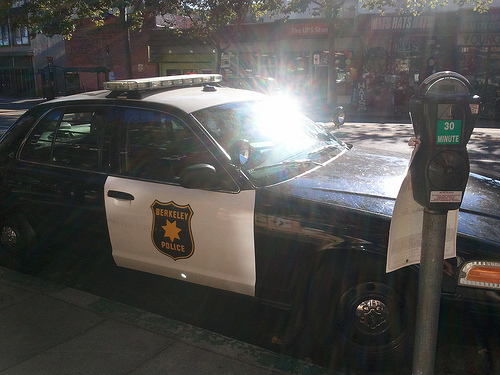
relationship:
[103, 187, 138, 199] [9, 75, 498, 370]
handle of car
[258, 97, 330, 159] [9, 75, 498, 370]
light shining on car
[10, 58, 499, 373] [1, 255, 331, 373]
police car next to sidewalk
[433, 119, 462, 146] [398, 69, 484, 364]
sign on parking meter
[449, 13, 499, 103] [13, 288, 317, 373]
storefront in front of sidewalk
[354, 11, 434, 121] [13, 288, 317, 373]
storefront in front of sidewalk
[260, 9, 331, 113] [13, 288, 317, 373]
storefront in front of sidewalk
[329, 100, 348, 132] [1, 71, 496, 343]
car mirror on side of police car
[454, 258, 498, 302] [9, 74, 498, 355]
orange light on side of vehicle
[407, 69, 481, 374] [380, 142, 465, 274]
parking meter with sign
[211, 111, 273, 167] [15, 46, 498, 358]
police officer in car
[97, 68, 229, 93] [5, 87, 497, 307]
lights on top of car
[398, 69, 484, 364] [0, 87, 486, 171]
parking meter beside road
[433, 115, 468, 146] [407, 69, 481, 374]
sign on parking meter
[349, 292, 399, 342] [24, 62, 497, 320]
rim of car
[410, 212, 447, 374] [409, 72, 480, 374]
pole holding meter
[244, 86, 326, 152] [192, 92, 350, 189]
sunlight glaring on windshield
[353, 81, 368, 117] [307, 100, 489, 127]
sign standing on sidewalk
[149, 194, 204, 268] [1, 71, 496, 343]
logo on police car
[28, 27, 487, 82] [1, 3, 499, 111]
buildings in background